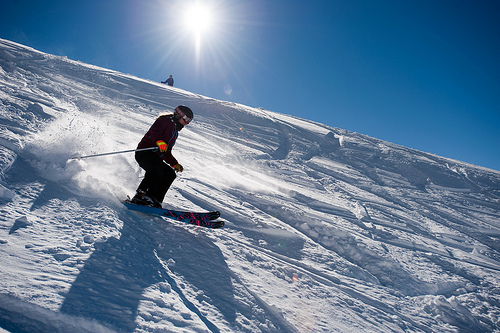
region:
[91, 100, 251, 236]
Down hill skier in black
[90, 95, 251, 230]
Skier in black snowsuit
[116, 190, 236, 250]
Blue red and black skies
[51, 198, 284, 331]
shadow in the white snow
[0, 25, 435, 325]
snowy hill with tracks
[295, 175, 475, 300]
Tracks in the snow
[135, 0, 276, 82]
bright sun in the sky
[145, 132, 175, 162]
Persons orange gloves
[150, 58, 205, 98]
Person looking downhill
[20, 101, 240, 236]
snow cloud behind the slier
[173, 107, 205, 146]
Person wearing black helmet.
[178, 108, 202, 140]
Person wearing goggles on face.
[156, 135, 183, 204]
Person wearing orange glove.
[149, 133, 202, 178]
Glove has yellow stripe.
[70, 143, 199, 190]
Person holding ski pole.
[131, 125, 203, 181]
Person wearing dark jacket.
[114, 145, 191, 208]
Person wearing black pants.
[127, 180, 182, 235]
Person wearing dark ski boots.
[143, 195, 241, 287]
2 skis on feet.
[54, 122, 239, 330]
Person skiing down mountainside.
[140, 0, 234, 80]
bright sun shining in blue sky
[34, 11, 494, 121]
bright blue sky with shining sun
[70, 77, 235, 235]
person wearing black skiing downhill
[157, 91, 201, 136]
black helmet on skiers head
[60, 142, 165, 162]
silver ski pole in snow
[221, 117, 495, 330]
white snow covered hill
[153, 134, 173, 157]
orange glove with yellow stripe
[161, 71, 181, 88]
skier in distance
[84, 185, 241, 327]
shadow of skier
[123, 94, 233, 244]
person in black snow suit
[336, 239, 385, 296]
part of a snow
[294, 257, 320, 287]
part of some lines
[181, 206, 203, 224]
part of some lines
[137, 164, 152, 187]
part of a trouser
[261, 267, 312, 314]
part of a snow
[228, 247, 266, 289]
part of a shade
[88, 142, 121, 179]
part of a hooker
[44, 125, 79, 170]
part of a splash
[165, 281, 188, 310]
edge of a shadow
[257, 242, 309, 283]
part of a snow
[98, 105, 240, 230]
man is skiing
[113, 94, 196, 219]
man is wearing black clothing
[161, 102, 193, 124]
man is wearing a helmet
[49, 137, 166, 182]
man is holding ski poles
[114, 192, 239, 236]
man has skis on his feet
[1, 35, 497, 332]
snow is on the slope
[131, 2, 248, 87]
the sun is bright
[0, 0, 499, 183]
the sky is blue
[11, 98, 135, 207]
the snow is flying in the air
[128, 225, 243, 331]
ski prints in the snow